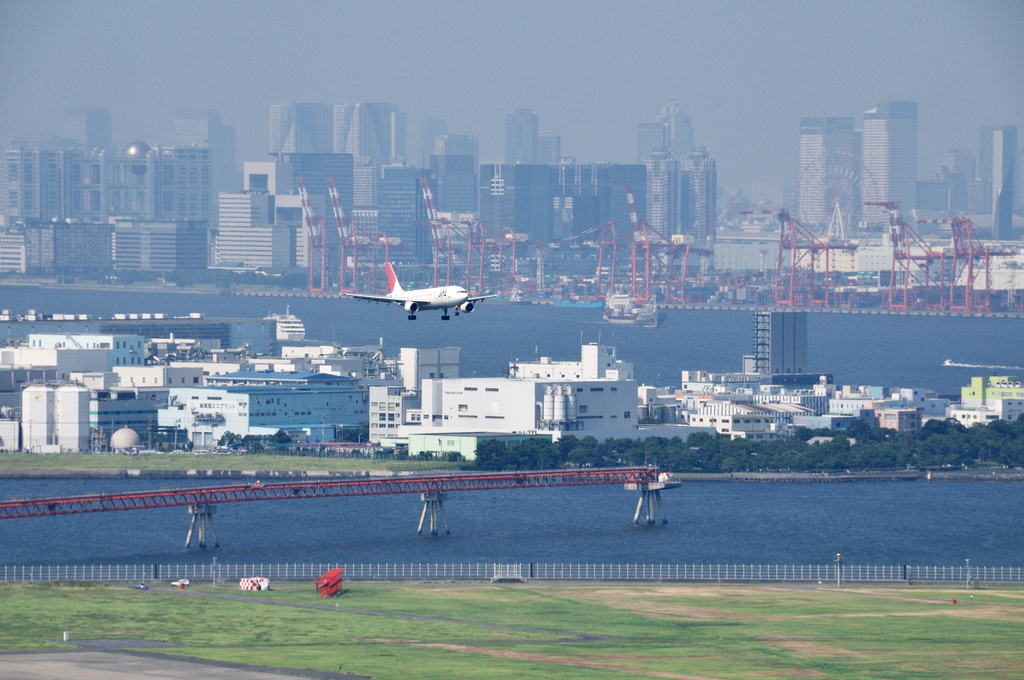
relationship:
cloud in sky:
[0, 0, 1024, 209] [0, 7, 1021, 94]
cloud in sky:
[0, 0, 1024, 209] [3, 1, 1022, 100]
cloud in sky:
[0, 0, 1024, 209] [9, 1, 1022, 120]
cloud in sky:
[0, 0, 1024, 209] [3, 4, 1022, 161]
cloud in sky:
[0, 0, 1024, 209] [838, 27, 915, 67]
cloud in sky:
[320, 17, 423, 75] [0, 2, 1022, 230]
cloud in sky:
[0, 0, 1024, 209] [0, 2, 1022, 230]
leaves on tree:
[461, 413, 1024, 471] [904, 417, 950, 460]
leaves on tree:
[461, 413, 1024, 471] [615, 431, 651, 471]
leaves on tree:
[461, 413, 1024, 471] [539, 419, 571, 465]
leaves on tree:
[487, 425, 514, 460] [488, 432, 509, 468]